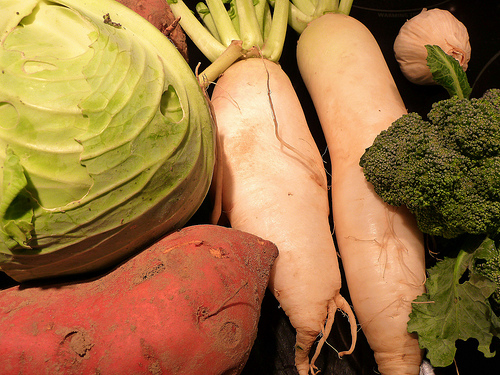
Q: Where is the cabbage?
A: On the left.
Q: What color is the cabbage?
A: Green and white.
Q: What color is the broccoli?
A: Green.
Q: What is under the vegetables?
A: The table.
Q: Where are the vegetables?
A: On the table.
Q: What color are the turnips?
A: White.